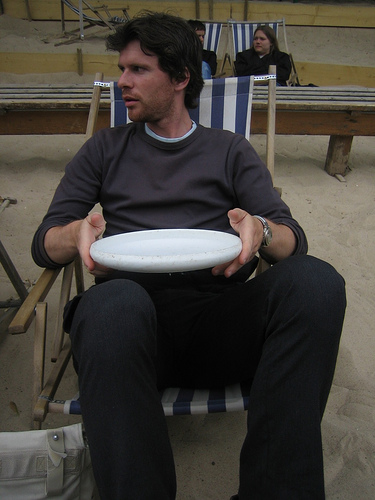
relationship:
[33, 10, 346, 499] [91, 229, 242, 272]
man holding frisbee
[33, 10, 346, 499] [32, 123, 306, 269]
man wearing a sweater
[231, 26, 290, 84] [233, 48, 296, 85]
woman wearing a jacket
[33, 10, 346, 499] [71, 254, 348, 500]
man wearing pants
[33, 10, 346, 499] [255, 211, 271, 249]
man wearing a watch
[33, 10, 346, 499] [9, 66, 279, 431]
man sitting in chair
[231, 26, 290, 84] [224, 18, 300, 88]
woman sitting in chair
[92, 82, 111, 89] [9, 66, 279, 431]
bracket on chair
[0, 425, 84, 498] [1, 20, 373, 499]
purse in sand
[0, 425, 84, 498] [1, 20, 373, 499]
purse on sand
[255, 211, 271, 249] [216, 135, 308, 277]
watch on arm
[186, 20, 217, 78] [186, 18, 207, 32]
man has hair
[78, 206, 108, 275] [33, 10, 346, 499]
hand of man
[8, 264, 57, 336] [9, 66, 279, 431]
arm rest of chair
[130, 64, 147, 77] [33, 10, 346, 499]
eye of man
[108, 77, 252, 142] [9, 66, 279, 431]
stripes on chair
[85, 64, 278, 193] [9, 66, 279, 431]
back of chair